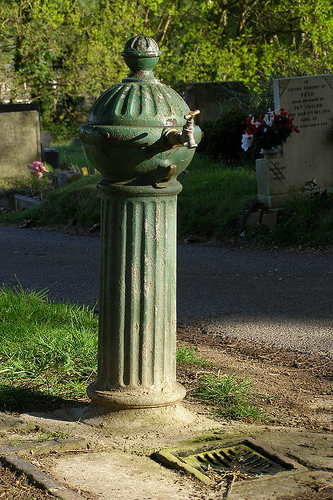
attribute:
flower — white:
[239, 132, 257, 151]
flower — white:
[265, 111, 277, 126]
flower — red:
[243, 115, 255, 130]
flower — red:
[278, 107, 300, 135]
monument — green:
[81, 37, 204, 430]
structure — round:
[125, 34, 162, 74]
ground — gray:
[2, 126, 331, 495]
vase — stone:
[256, 145, 285, 196]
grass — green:
[0, 285, 194, 373]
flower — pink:
[32, 161, 46, 176]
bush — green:
[202, 105, 256, 167]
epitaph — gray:
[284, 79, 329, 134]